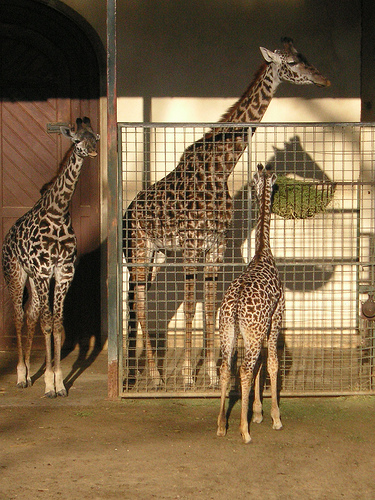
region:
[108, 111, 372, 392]
The fence is metal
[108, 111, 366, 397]
The fence is gray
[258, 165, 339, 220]
Hay in a feed bucket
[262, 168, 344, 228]
The hay is green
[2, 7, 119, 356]
The door is tall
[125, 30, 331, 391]
The giraffe is standing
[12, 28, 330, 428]
There are three giraffes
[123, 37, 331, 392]
The giraffe is brown and white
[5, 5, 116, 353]
The large door is dark brown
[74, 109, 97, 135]
The giraffe has black horns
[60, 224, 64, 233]
brown spot on giraffe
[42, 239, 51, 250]
brown spot on giraffe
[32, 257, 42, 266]
brown spot on giraffe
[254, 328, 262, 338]
brown spot on giraffe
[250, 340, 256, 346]
brown spot on giraffe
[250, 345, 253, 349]
brown spot on giraffe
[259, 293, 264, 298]
brown spot on giraffe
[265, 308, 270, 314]
brown spot on giraffe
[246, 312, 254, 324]
brown spot on giraffe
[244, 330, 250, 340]
brown spot on giraffe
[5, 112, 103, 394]
a baby spotted giraffe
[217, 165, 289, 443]
a baby spotted giraffe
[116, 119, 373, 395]
a metal wire divider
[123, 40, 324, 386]
a large spotted giraffe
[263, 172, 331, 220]
a large green leaf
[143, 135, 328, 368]
a giraffe's cast shadow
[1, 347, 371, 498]
a plain concrete floor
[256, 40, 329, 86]
a giraffe's raised head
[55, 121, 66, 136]
a giraffe's right ear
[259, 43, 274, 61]
a giraffe's right ear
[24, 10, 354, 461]
three giraffes standing up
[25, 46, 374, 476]
three giraffes standing outside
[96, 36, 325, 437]
a tall giraffe fenced in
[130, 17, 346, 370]
a giraffe behind a fence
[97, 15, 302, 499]
a tall giraffe behind a fence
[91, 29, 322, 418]
a giraffe behind a metal fence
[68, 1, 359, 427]
a metal fence witha giraffe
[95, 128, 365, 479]
a short giraffe standing outside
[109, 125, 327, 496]
a young giraffe standing outside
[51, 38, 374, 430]
a tall metal fence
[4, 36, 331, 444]
the three giraffe's standing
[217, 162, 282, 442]
the smallest giraffe standing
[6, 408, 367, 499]
the dirt on the ground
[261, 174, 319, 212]
the green grass up high for the giraffe's to eat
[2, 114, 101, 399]
the giraffe standing to the left of the group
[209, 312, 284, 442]
the four legs on the smallest giraffe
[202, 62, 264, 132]
the mane on the tallest giraffe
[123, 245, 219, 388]
the legs on the tallest giraffe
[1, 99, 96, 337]
the brown wooden door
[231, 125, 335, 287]
the shadow on the wall